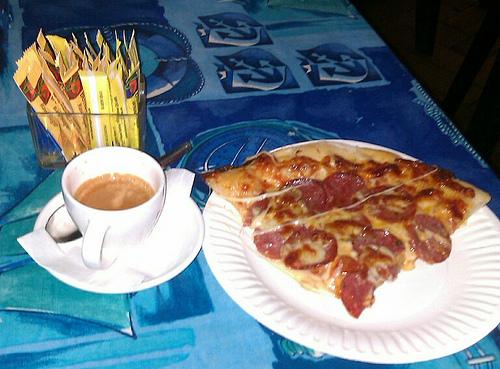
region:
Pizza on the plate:
[253, 123, 409, 310]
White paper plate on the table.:
[206, 245, 484, 367]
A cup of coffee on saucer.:
[63, 173, 167, 269]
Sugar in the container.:
[18, 18, 165, 143]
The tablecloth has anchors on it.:
[211, 38, 305, 115]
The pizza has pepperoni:
[304, 167, 369, 242]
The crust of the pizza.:
[226, 140, 350, 185]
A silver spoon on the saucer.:
[39, 188, 82, 248]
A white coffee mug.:
[53, 142, 168, 260]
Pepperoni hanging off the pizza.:
[331, 258, 387, 322]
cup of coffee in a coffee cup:
[65, 148, 163, 265]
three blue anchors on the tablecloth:
[210, 12, 365, 85]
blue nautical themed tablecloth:
[5, 2, 495, 357]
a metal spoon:
[42, 139, 190, 236]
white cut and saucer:
[36, 145, 202, 292]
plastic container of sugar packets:
[13, 30, 146, 148]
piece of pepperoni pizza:
[210, 140, 489, 312]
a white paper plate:
[201, 138, 498, 365]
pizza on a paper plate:
[201, 134, 498, 359]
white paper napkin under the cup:
[17, 167, 193, 292]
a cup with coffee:
[37, 148, 172, 236]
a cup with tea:
[41, 138, 164, 270]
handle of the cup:
[70, 219, 131, 271]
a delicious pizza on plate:
[234, 128, 489, 325]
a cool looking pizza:
[231, 125, 430, 287]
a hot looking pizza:
[219, 137, 499, 320]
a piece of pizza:
[221, 145, 495, 325]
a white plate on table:
[204, 135, 462, 358]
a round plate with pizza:
[198, 150, 497, 364]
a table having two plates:
[43, 140, 493, 362]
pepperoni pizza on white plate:
[197, 138, 493, 317]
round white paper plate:
[199, 135, 497, 367]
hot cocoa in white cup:
[43, 140, 172, 272]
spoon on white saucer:
[36, 133, 212, 242]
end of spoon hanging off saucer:
[147, 131, 196, 170]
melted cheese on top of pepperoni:
[200, 140, 490, 317]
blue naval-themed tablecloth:
[0, 0, 497, 367]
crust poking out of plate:
[200, 168, 216, 189]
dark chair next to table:
[443, 0, 498, 169]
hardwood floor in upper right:
[351, 0, 498, 175]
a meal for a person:
[22, 47, 498, 315]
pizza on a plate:
[222, 129, 482, 333]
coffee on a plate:
[29, 153, 196, 290]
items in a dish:
[13, 35, 163, 154]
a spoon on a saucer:
[24, 138, 197, 248]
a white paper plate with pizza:
[221, 224, 477, 354]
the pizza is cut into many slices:
[232, 138, 472, 308]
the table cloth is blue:
[179, 20, 416, 131]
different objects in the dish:
[16, 40, 148, 107]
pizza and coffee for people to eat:
[17, 19, 461, 308]